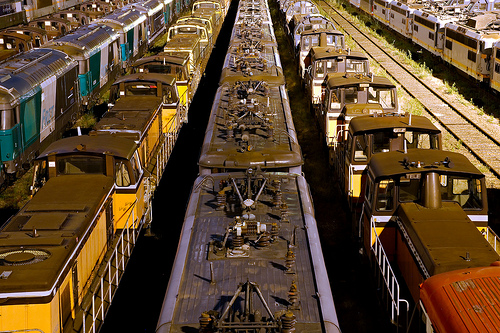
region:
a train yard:
[18, 4, 493, 331]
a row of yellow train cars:
[16, 24, 201, 327]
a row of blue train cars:
[7, 3, 153, 155]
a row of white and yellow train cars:
[407, 12, 487, 97]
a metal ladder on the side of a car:
[101, 182, 148, 331]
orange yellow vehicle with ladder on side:
[292, 16, 470, 317]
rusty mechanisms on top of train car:
[208, 69, 274, 320]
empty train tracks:
[327, 10, 490, 180]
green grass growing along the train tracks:
[337, 6, 483, 111]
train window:
[55, 150, 118, 187]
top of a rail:
[232, 143, 267, 225]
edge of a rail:
[317, 279, 330, 324]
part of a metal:
[260, 291, 284, 316]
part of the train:
[163, 255, 194, 288]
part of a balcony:
[99, 264, 122, 298]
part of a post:
[91, 285, 103, 320]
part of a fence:
[379, 260, 396, 308]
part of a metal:
[387, 272, 405, 297]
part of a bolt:
[460, 247, 475, 267]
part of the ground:
[0, 159, 32, 193]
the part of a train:
[155, 166, 335, 331]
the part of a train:
[198, 72, 307, 169]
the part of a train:
[222, 39, 282, 80]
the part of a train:
[226, 18, 276, 42]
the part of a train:
[233, 5, 266, 27]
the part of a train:
[444, 16, 490, 84]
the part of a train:
[410, 3, 452, 60]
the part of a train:
[388, 0, 411, 42]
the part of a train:
[317, 67, 398, 137]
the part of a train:
[338, 107, 445, 195]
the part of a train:
[14, 166, 131, 327]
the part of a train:
[53, 86, 157, 208]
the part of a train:
[353, 128, 495, 321]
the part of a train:
[301, 39, 375, 100]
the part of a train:
[293, 28, 352, 78]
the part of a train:
[290, 7, 335, 54]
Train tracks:
[377, 47, 409, 82]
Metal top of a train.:
[236, 71, 293, 259]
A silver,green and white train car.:
[0, 54, 69, 146]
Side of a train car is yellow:
[85, 240, 100, 257]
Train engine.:
[1, 123, 171, 328]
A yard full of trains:
[3, 2, 468, 316]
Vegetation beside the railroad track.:
[386, 45, 416, 60]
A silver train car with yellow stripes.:
[410, 11, 445, 56]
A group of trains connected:
[3, 0, 169, 64]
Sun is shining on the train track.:
[338, 11, 445, 111]